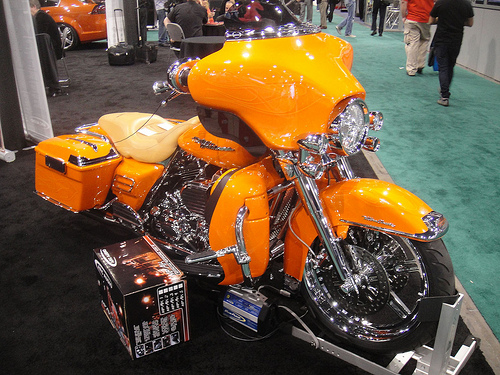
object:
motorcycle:
[33, 24, 453, 354]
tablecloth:
[171, 35, 224, 49]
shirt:
[431, 1, 469, 50]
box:
[92, 239, 190, 361]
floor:
[1, 152, 369, 374]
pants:
[436, 44, 458, 106]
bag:
[104, 42, 136, 65]